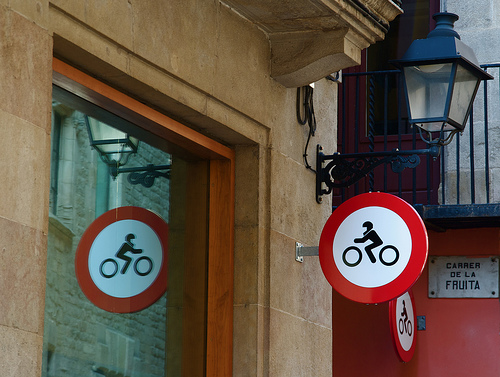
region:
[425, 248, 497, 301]
white sign in Spanish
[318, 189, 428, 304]
red and white sign about motorcycling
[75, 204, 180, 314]
reflection of red and white sign about motorcycling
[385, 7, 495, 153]
an inactive black streetlight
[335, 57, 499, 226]
a black metal railing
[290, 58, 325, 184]
black wires coming out of the building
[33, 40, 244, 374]
wooden frame of window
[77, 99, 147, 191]
reflection of inactive black street light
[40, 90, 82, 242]
reflection of a window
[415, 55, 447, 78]
the white bulb of an inactive street light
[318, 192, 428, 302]
red and white bicyclist sign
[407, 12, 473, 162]
black wrought iron street lamp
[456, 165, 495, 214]
black iron railing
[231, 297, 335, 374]
tan building blocks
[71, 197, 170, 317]
reflection of bicycle sign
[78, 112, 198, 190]
reflection of street lamp in window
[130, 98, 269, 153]
brown wood trim around window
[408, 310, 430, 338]
grey metal bracket holding bicycle sign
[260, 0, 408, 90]
overhang of a block building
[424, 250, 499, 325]
black and white sign on orange building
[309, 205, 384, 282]
A sign for bikers.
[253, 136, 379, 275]
A sign for bikers.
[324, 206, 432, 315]
A sign for bikers.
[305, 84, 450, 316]
A sign for bikers.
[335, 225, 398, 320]
A sign for bikers.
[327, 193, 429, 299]
The sign has a bicycle on it.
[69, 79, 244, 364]
The building has a window.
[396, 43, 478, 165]
The lamp latern is black.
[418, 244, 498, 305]
A white sign on the side of the building.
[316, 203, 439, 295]
The sign is red black and white.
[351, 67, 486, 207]
The railing is made of iron.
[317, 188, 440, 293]
The sign is shaped like a circle.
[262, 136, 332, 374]
The building is beige and brown.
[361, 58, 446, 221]
the door is burgundy.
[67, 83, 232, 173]
The trimming on the window is wooden.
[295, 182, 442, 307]
traffic sign mounted on a building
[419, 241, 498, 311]
white sign on a building wall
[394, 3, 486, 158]
black light fixture on side of a building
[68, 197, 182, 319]
reflection of a sign in window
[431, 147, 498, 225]
black iron balcony on a building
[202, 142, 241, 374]
wooden frame of a window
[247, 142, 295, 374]
beige stone on a building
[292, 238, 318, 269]
silver mount on a building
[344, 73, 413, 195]
red door to second floor of a building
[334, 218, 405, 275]
image of a motorcyclist on sign